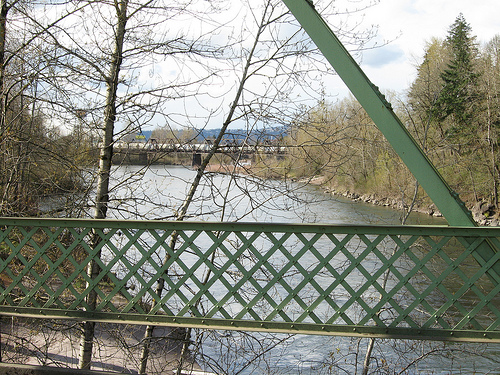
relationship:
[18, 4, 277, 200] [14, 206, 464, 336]
trees behind fence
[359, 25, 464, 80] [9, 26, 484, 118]
clouds in sky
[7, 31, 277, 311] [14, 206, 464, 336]
trees behind fence